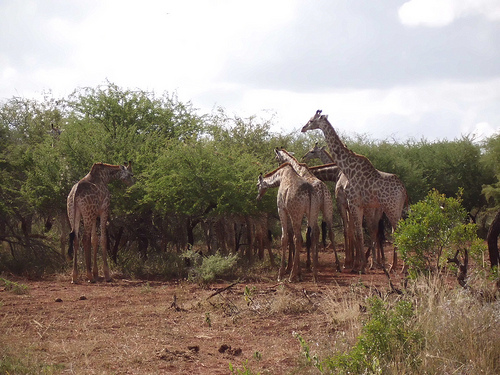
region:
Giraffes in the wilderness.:
[234, 118, 431, 285]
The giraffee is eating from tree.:
[261, 105, 334, 270]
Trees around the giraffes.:
[101, 90, 413, 262]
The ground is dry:
[91, 264, 303, 339]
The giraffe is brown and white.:
[276, 153, 338, 255]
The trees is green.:
[104, 108, 236, 226]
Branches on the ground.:
[194, 254, 300, 311]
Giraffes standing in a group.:
[248, 136, 410, 274]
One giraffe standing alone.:
[39, 138, 150, 275]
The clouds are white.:
[108, 28, 418, 140]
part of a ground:
[198, 296, 235, 344]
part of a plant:
[357, 305, 391, 362]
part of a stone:
[207, 325, 233, 361]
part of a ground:
[213, 316, 228, 339]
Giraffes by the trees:
[74, 111, 406, 277]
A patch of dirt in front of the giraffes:
[7, 283, 389, 374]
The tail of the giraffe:
[306, 186, 311, 252]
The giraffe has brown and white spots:
[351, 162, 398, 204]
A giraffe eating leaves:
[68, 155, 130, 281]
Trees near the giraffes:
[142, 122, 266, 263]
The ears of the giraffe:
[313, 110, 329, 121]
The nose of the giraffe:
[301, 125, 308, 132]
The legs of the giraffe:
[71, 214, 111, 279]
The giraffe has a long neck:
[319, 128, 359, 170]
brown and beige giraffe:
[45, 151, 136, 306]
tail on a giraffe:
[65, 182, 91, 262]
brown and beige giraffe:
[247, 160, 323, 280]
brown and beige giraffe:
[306, 107, 408, 283]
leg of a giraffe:
[300, 220, 335, 281]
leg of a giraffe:
[285, 222, 315, 287]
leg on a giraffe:
[276, 216, 291, 271]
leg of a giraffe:
[85, 220, 107, 290]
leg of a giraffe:
[63, 235, 86, 292]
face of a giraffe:
[284, 102, 336, 152]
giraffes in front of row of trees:
[3, 61, 489, 296]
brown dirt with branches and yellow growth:
[10, 242, 352, 363]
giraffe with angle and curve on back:
[60, 155, 135, 285]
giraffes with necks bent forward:
[250, 140, 340, 286]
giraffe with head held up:
[295, 105, 407, 280]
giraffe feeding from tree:
[250, 160, 315, 285]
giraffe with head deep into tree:
[65, 155, 140, 195]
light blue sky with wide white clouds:
[6, 5, 493, 140]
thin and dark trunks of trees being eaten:
[120, 120, 272, 275]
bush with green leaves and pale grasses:
[352, 192, 492, 368]